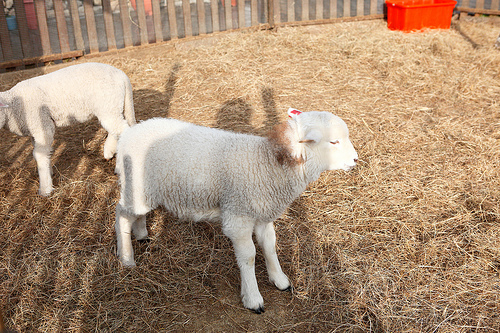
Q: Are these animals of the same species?
A: Yes, all the animals are sheep.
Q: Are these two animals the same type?
A: Yes, all the animals are sheep.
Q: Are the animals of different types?
A: No, all the animals are sheep.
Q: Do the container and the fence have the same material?
A: No, the container is made of plastic and the fence is made of wood.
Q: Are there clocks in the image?
A: No, there are no clocks.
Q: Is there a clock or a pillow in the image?
A: No, there are no clocks or pillows.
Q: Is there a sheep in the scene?
A: Yes, there is a sheep.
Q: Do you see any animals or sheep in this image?
A: Yes, there is a sheep.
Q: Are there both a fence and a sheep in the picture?
A: Yes, there are both a sheep and a fence.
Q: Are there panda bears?
A: No, there are no panda bears.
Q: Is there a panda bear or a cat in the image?
A: No, there are no panda bears or cats.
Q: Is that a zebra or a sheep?
A: That is a sheep.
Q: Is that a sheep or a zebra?
A: That is a sheep.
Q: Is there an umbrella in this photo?
A: No, there are no umbrellas.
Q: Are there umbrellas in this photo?
A: No, there are no umbrellas.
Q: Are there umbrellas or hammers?
A: No, there are no umbrellas or hammers.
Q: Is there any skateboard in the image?
A: No, there are no skateboards.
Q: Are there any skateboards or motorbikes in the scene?
A: No, there are no skateboards or motorbikes.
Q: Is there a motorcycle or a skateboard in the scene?
A: No, there are no skateboards or motorcycles.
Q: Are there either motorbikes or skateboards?
A: No, there are no skateboards or motorbikes.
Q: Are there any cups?
A: No, there are no cups.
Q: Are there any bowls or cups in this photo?
A: No, there are no cups or bowls.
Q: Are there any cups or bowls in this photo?
A: No, there are no cups or bowls.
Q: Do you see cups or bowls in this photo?
A: No, there are no cups or bowls.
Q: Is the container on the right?
A: Yes, the container is on the right of the image.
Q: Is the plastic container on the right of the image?
A: Yes, the container is on the right of the image.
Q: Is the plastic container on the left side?
A: No, the container is on the right of the image.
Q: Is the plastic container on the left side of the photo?
A: No, the container is on the right of the image.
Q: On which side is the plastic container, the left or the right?
A: The container is on the right of the image.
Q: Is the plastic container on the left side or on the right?
A: The container is on the right of the image.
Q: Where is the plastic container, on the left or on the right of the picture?
A: The container is on the right of the image.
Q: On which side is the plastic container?
A: The container is on the right of the image.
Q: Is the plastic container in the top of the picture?
A: Yes, the container is in the top of the image.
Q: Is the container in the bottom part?
A: No, the container is in the top of the image.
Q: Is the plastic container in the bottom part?
A: No, the container is in the top of the image.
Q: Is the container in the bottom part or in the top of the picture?
A: The container is in the top of the image.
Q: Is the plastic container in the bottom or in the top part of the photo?
A: The container is in the top of the image.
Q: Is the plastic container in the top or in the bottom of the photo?
A: The container is in the top of the image.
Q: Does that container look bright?
A: Yes, the container is bright.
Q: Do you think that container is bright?
A: Yes, the container is bright.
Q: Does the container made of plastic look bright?
A: Yes, the container is bright.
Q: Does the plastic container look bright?
A: Yes, the container is bright.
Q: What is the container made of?
A: The container is made of plastic.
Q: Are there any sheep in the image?
A: Yes, there is a sheep.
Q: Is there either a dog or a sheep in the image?
A: Yes, there is a sheep.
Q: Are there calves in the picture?
A: No, there are no calves.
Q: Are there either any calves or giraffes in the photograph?
A: No, there are no calves or giraffes.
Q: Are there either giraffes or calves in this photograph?
A: No, there are no calves or giraffes.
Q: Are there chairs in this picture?
A: No, there are no chairs.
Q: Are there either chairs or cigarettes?
A: No, there are no chairs or cigarettes.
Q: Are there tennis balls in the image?
A: No, there are no tennis balls.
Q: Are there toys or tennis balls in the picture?
A: No, there are no tennis balls or toys.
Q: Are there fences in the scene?
A: Yes, there is a fence.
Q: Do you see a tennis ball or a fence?
A: Yes, there is a fence.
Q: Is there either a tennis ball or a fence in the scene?
A: Yes, there is a fence.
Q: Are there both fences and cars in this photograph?
A: No, there is a fence but no cars.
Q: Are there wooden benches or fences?
A: Yes, there is a wood fence.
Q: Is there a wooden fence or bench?
A: Yes, there is a wood fence.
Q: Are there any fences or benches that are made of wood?
A: Yes, the fence is made of wood.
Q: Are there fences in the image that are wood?
A: Yes, there is a wood fence.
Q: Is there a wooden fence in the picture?
A: Yes, there is a wood fence.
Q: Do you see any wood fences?
A: Yes, there is a wood fence.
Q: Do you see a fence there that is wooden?
A: Yes, there is a fence that is wooden.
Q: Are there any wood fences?
A: Yes, there is a fence that is made of wood.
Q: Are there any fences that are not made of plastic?
A: Yes, there is a fence that is made of wood.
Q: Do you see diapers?
A: No, there are no diapers.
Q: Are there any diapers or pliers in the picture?
A: No, there are no diapers or pliers.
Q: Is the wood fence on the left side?
A: Yes, the fence is on the left of the image.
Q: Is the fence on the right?
A: No, the fence is on the left of the image.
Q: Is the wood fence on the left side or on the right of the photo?
A: The fence is on the left of the image.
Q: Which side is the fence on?
A: The fence is on the left of the image.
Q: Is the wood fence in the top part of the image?
A: Yes, the fence is in the top of the image.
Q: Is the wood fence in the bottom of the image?
A: No, the fence is in the top of the image.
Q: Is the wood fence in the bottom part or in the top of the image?
A: The fence is in the top of the image.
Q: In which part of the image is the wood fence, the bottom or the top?
A: The fence is in the top of the image.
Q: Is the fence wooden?
A: Yes, the fence is wooden.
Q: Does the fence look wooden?
A: Yes, the fence is wooden.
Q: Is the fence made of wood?
A: Yes, the fence is made of wood.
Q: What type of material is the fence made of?
A: The fence is made of wood.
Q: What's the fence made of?
A: The fence is made of wood.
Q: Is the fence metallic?
A: No, the fence is wooden.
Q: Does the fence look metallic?
A: No, the fence is wooden.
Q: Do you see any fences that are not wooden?
A: No, there is a fence but it is wooden.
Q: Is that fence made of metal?
A: No, the fence is made of wood.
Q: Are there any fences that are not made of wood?
A: No, there is a fence but it is made of wood.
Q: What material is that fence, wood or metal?
A: The fence is made of wood.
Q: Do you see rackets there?
A: No, there are no rackets.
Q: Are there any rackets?
A: No, there are no rackets.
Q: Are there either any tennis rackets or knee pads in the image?
A: No, there are no tennis rackets or knee pads.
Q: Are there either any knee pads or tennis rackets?
A: No, there are no tennis rackets or knee pads.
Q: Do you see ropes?
A: No, there are no ropes.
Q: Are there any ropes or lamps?
A: No, there are no ropes or lamps.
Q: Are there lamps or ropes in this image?
A: No, there are no ropes or lamps.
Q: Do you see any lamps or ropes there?
A: No, there are no ropes or lamps.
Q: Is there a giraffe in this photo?
A: No, there are no giraffes.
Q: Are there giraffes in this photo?
A: No, there are no giraffes.